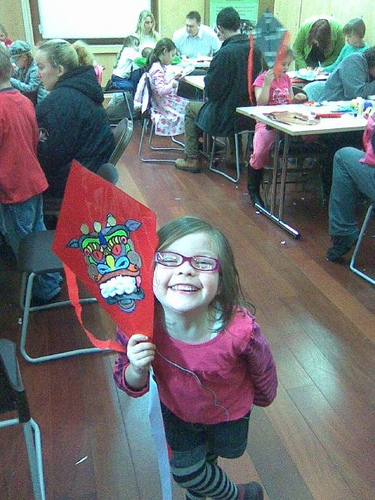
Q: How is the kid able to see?
A: With eyeglasses.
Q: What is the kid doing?
A: Posing for a picture.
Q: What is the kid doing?
A: Smiling.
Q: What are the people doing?
A: Crafting kites.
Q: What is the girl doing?
A: Holding a kite.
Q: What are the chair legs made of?
A: Metal.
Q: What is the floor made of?
A: Wood.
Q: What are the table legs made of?
A: Metal.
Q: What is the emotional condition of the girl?
A: Happiness.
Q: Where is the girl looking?
A: At the camera.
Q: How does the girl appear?
A: Happy.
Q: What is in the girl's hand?
A: A kite.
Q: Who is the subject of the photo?
A: A little girl.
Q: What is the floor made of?
A: Wood.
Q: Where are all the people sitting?
A: At tables.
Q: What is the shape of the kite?
A: Diamond.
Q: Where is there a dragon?
A: On kite.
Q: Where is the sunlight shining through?
A: Window.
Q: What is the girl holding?
A: A kite.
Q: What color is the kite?
A: Red.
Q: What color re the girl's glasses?
A: Pink.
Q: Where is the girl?
A: In school.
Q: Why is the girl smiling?
A: She is happy.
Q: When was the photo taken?
A: Daytime.